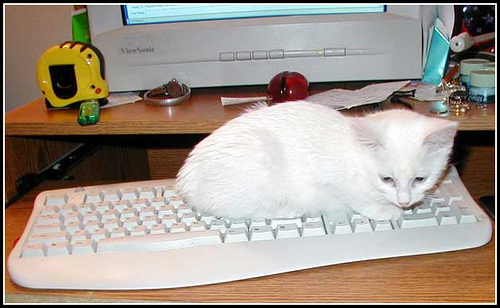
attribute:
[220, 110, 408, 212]
cat — white, lying, small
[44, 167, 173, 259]
keyboard — white, edge, part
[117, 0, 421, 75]
monitor — computer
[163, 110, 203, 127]
desk — tan, wood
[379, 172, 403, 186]
eye — left eye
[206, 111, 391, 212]
kitten — white, sitting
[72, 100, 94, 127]
watch — silver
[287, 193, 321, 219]
stomach — part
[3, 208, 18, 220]
table — part, edge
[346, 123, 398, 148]
ear — part